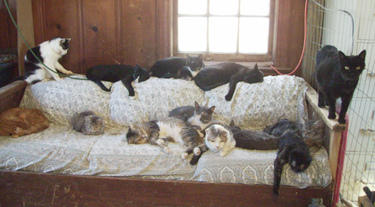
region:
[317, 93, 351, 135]
the cat is on the arm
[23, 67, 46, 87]
the cat is sitting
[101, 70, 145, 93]
the cat is laying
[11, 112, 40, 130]
the cat is curled up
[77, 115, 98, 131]
the cat is gray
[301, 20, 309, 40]
the cord is red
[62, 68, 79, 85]
the cord is green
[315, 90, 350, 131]
the cat is standing on the arm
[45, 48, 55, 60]
the cat is white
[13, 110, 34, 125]
the cat is orange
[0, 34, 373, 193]
The cats on the bed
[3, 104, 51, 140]
The cat is the color brown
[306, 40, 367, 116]
The cat is the color black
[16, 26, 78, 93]
The cat is grey and white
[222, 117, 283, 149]
The cat is the color grey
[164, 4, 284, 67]
The window is open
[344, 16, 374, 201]
The wall is made of metal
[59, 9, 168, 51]
The wall is made of wood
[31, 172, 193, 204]
The bed frame is made of wood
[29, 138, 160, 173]
The mattress on the bed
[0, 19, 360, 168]
group of cats on a couch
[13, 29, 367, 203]
group of cats in a room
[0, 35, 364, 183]
room infested with cats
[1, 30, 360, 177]
cat infestation in room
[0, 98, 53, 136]
orange cat on couch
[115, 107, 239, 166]
three cats laying on couch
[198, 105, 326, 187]
several cats laying on couch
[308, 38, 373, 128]
black cat walking on couch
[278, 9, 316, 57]
orange extension wire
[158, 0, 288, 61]
square window on wall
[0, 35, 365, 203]
a lot of cats on a couch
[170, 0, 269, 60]
a window behind the couch of cats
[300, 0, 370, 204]
a tall cage next to the couch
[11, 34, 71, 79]
a white and black cat pawing a green cord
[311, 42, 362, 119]
a black cat on arm of the couch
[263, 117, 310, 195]
a cat with its arm hanging down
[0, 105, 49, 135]
orange cat curled up on couch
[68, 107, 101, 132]
small tabby cat sitting on the couch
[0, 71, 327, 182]
the material covering the couch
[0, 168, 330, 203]
wood panel on bottom of couch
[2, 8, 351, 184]
a couch covered in cats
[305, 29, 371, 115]
a black cat on a futon arm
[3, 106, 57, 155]
an orange cat curled in a ball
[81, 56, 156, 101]
a black and white cat draped on a cushion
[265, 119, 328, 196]
a grey and brown cat reaching for the ground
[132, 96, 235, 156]
a pile of cats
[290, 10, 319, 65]
an orange extension cord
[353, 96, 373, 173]
a fence to keep cats in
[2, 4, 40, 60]
a green extension cord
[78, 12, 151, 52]
a wood paneled wall